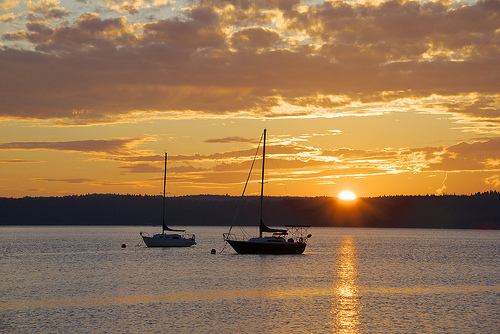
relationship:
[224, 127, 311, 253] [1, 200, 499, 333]
boats moored in bay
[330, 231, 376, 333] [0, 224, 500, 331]
reflection in water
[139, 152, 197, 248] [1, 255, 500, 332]
sail boats moored in water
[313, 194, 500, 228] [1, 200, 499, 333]
mangoves around bay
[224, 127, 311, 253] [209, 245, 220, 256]
sailboats tied to buoy's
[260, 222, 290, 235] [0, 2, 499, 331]
sails are down for night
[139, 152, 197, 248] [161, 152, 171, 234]
sailboat has a short mast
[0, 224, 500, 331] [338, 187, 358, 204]
water reflecting sun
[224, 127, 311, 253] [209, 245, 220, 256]
sailboat tied to buoy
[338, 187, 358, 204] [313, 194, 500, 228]
sun setting behind trees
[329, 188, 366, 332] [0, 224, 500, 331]
sun is reflecting off water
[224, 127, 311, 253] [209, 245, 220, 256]
sailboats moored to buoy's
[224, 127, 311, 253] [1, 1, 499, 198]
sailboats at sunset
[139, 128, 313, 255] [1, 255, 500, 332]
sailboats moored in water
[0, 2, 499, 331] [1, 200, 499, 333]
sunrise in bay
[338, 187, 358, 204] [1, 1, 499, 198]
sun going down slowly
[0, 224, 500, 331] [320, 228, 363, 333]
water reflecting sunlight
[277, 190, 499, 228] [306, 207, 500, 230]
mangroves lining shore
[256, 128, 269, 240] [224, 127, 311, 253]
long mast on sailboat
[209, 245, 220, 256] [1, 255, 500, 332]
buoy in water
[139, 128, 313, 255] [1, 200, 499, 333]
sailboats moored in bay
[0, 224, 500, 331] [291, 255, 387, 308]
water makes cross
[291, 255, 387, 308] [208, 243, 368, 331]
cross in water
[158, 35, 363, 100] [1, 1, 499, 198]
clouds in sky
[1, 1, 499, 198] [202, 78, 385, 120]
sky between clouds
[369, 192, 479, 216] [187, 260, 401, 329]
hill at edge of water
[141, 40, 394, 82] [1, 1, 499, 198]
clouds in sky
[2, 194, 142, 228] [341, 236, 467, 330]
trees at edge of water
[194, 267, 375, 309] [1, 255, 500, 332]
water with ripples